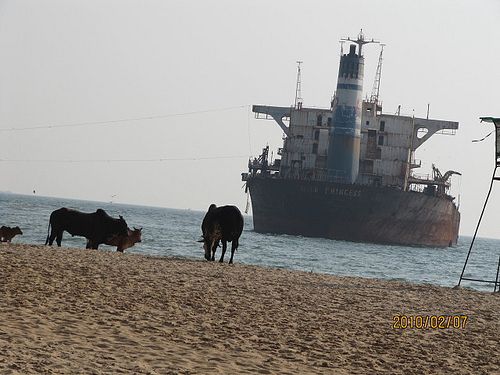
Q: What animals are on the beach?
A: Cows.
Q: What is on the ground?
A: Sand.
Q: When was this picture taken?
A: 2010/02/07.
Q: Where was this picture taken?
A: Beach.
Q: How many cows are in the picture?
A: Four.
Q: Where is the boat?
A: On the ocean.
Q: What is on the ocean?
A: Boat.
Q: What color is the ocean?
A: Blue.